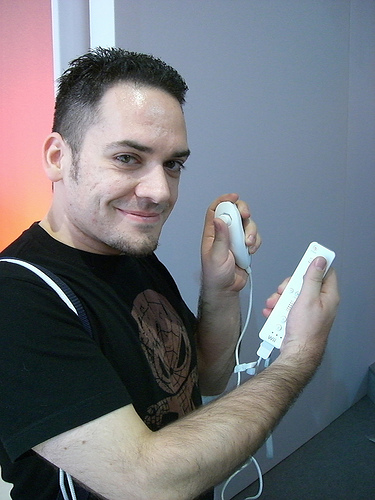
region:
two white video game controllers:
[215, 202, 331, 356]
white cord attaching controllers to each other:
[226, 269, 268, 498]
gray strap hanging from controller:
[261, 357, 281, 459]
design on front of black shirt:
[121, 292, 198, 425]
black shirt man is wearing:
[8, 215, 219, 498]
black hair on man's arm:
[162, 353, 325, 490]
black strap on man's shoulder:
[4, 247, 91, 324]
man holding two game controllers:
[4, 51, 349, 497]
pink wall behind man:
[2, 3, 51, 253]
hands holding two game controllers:
[200, 187, 335, 367]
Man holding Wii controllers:
[5, 21, 358, 486]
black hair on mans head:
[49, 37, 206, 128]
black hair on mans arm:
[251, 373, 281, 416]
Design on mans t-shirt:
[124, 287, 194, 412]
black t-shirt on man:
[2, 251, 190, 414]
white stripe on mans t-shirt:
[1, 251, 78, 337]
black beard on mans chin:
[110, 230, 168, 258]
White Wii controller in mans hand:
[253, 235, 341, 358]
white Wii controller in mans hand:
[205, 197, 262, 282]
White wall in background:
[204, 10, 360, 154]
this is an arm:
[130, 342, 265, 492]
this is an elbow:
[151, 437, 157, 483]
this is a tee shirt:
[97, 315, 121, 355]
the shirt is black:
[109, 341, 186, 447]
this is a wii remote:
[227, 235, 317, 336]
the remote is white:
[235, 247, 295, 342]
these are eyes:
[106, 158, 182, 178]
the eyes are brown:
[99, 150, 195, 213]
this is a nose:
[138, 181, 176, 196]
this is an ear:
[47, 149, 61, 203]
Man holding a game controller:
[2, 43, 348, 496]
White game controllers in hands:
[196, 189, 344, 370]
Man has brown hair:
[39, 42, 193, 259]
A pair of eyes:
[108, 146, 188, 178]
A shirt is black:
[1, 218, 214, 498]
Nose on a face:
[137, 166, 172, 212]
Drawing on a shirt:
[127, 283, 207, 429]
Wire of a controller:
[214, 268, 276, 498]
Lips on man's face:
[112, 202, 168, 230]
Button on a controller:
[213, 210, 235, 232]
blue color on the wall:
[231, 63, 307, 117]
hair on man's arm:
[159, 432, 236, 444]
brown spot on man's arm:
[57, 439, 96, 452]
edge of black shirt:
[37, 411, 111, 437]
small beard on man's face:
[109, 231, 164, 257]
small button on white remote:
[200, 207, 249, 235]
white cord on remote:
[231, 301, 253, 351]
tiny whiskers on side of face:
[67, 152, 83, 179]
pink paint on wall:
[11, 93, 38, 127]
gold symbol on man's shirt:
[128, 287, 199, 389]